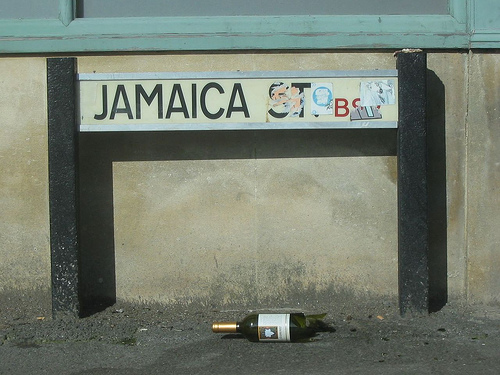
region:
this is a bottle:
[208, 296, 308, 347]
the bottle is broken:
[205, 296, 337, 350]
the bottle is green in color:
[291, 312, 306, 336]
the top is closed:
[208, 317, 239, 333]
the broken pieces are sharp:
[313, 306, 331, 327]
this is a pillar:
[398, 145, 440, 314]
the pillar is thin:
[398, 132, 431, 299]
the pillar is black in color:
[391, 187, 426, 271]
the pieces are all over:
[110, 312, 185, 344]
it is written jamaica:
[96, 72, 256, 122]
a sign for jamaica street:
[75, 72, 400, 127]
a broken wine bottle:
[212, 310, 310, 342]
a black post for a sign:
[45, 55, 81, 320]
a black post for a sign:
[394, 49, 425, 314]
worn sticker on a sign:
[359, 80, 395, 107]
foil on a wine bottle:
[211, 321, 237, 331]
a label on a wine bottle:
[257, 312, 290, 342]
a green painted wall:
[1, 18, 498, 53]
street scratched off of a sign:
[269, 82, 308, 120]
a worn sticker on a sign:
[303, 84, 330, 116]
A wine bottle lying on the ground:
[220, 295, 316, 344]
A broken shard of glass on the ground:
[307, 311, 333, 334]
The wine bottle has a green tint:
[242, 308, 314, 347]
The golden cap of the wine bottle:
[211, 315, 241, 339]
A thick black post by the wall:
[393, 38, 449, 315]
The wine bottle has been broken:
[205, 303, 334, 345]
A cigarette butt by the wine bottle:
[375, 309, 386, 321]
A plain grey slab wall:
[161, 182, 387, 274]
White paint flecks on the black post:
[54, 248, 86, 315]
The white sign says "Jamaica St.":
[62, 70, 419, 134]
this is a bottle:
[210, 312, 316, 354]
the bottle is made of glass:
[253, 312, 311, 349]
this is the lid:
[213, 317, 239, 334]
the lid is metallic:
[208, 320, 238, 333]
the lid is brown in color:
[208, 315, 235, 335]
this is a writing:
[96, 87, 249, 113]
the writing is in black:
[93, 86, 235, 110]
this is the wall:
[138, 166, 338, 266]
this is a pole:
[382, 52, 438, 352]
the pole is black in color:
[398, 134, 424, 216]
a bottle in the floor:
[200, 293, 361, 362]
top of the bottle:
[208, 318, 242, 340]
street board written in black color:
[47, 60, 448, 150]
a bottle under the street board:
[164, 58, 349, 365]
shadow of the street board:
[432, 80, 448, 308]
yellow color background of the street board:
[86, 85, 398, 120]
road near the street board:
[153, 342, 385, 367]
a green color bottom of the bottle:
[235, 315, 301, 342]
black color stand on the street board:
[35, 53, 447, 318]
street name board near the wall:
[100, 50, 392, 216]